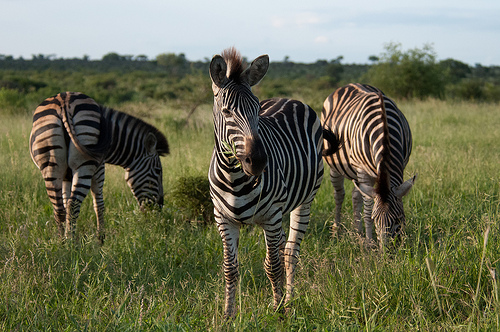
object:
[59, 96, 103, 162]
tail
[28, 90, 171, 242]
zebra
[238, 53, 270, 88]
ears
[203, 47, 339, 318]
zebra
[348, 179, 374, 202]
ears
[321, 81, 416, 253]
zebra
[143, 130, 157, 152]
ear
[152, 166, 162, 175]
eye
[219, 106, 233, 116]
eye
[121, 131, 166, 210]
head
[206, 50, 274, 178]
head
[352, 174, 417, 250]
head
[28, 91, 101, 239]
rear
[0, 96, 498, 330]
grass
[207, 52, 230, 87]
ear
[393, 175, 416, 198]
ear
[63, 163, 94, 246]
legs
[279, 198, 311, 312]
legs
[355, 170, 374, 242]
legs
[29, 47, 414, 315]
zebras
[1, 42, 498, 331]
field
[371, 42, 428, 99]
trees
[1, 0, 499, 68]
sky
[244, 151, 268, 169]
nose